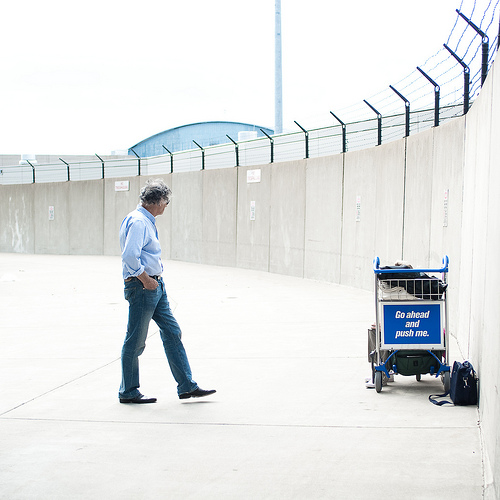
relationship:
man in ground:
[126, 188, 206, 409] [4, 258, 411, 495]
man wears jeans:
[126, 188, 206, 409] [123, 283, 194, 395]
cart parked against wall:
[368, 260, 458, 395] [288, 144, 490, 348]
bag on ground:
[448, 359, 479, 404] [4, 258, 411, 495]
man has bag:
[126, 188, 206, 409] [448, 359, 479, 404]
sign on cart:
[379, 305, 447, 347] [368, 260, 458, 395]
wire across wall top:
[2, 131, 309, 184] [7, 165, 291, 189]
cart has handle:
[368, 260, 458, 395] [372, 261, 454, 280]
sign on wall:
[243, 169, 264, 186] [1, 181, 480, 296]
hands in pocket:
[129, 272, 165, 293] [139, 280, 164, 301]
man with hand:
[126, 188, 206, 409] [124, 226, 158, 292]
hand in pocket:
[124, 226, 158, 292] [139, 280, 164, 301]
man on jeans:
[126, 188, 206, 409] [123, 283, 194, 395]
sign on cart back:
[379, 305, 447, 347] [378, 279, 447, 354]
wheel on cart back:
[370, 371, 454, 394] [378, 279, 447, 354]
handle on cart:
[372, 261, 454, 280] [368, 260, 458, 395]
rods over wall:
[87, 149, 180, 178] [1, 181, 480, 296]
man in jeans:
[126, 188, 206, 409] [123, 283, 194, 395]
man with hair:
[126, 188, 206, 409] [141, 181, 170, 211]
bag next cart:
[448, 359, 479, 404] [368, 260, 458, 395]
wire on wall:
[2, 131, 309, 184] [1, 181, 480, 296]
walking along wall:
[81, 345, 252, 422] [1, 181, 480, 296]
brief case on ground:
[448, 359, 479, 404] [4, 258, 411, 495]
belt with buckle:
[126, 273, 171, 285] [155, 273, 165, 287]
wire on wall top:
[2, 131, 309, 184] [7, 165, 291, 189]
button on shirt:
[154, 234, 164, 278] [123, 215, 161, 277]